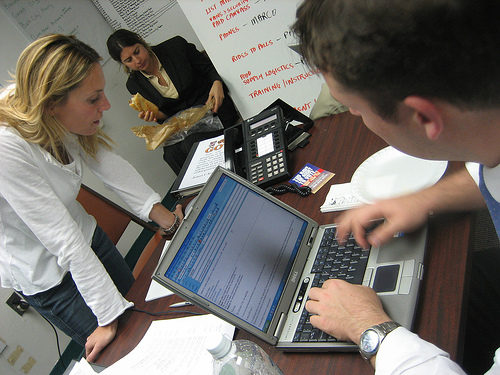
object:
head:
[106, 29, 149, 70]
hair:
[106, 29, 151, 76]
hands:
[306, 279, 385, 341]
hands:
[334, 197, 427, 249]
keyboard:
[292, 219, 385, 342]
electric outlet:
[6, 291, 30, 317]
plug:
[17, 300, 30, 312]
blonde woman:
[0, 33, 183, 362]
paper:
[102, 313, 236, 374]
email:
[164, 173, 309, 333]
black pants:
[163, 101, 240, 177]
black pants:
[14, 225, 135, 352]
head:
[19, 35, 111, 136]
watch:
[359, 321, 402, 367]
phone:
[223, 106, 293, 189]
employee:
[107, 28, 240, 176]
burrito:
[129, 92, 159, 117]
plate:
[350, 145, 449, 205]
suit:
[125, 36, 225, 126]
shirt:
[1, 83, 163, 327]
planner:
[289, 0, 500, 317]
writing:
[175, 0, 327, 120]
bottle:
[204, 332, 284, 374]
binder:
[178, 134, 225, 189]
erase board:
[178, 0, 326, 122]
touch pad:
[372, 264, 399, 292]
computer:
[151, 165, 429, 353]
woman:
[0, 29, 226, 362]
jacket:
[126, 43, 227, 125]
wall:
[0, 0, 202, 375]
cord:
[38, 313, 63, 375]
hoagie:
[128, 93, 158, 118]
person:
[288, 0, 499, 375]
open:
[217, 255, 248, 356]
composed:
[290, 278, 340, 375]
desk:
[83, 110, 477, 375]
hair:
[0, 32, 117, 163]